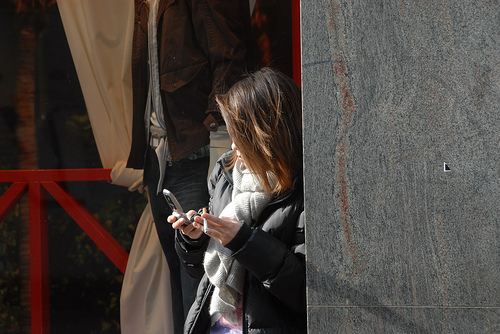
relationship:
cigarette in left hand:
[202, 206, 209, 234] [193, 214, 242, 246]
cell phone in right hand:
[163, 188, 193, 224] [166, 210, 203, 239]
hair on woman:
[214, 67, 301, 198] [168, 66, 307, 333]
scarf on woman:
[203, 158, 279, 316] [168, 66, 307, 333]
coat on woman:
[175, 151, 307, 333] [168, 66, 307, 333]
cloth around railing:
[56, 0, 175, 333] [0, 167, 131, 332]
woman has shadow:
[168, 66, 307, 333] [308, 261, 430, 333]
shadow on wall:
[308, 261, 430, 333] [301, 0, 500, 333]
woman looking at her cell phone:
[168, 66, 307, 333] [163, 188, 193, 224]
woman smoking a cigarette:
[168, 66, 307, 333] [202, 206, 209, 234]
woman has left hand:
[168, 66, 307, 333] [193, 214, 242, 246]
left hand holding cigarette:
[193, 214, 242, 246] [202, 206, 209, 234]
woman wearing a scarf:
[168, 66, 307, 333] [203, 158, 279, 316]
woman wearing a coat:
[168, 66, 307, 333] [175, 151, 307, 333]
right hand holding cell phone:
[166, 210, 203, 239] [163, 188, 193, 224]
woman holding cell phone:
[168, 66, 307, 333] [163, 188, 193, 224]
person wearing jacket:
[128, 1, 249, 333] [124, 2, 247, 171]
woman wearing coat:
[168, 66, 307, 333] [175, 151, 307, 333]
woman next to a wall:
[168, 66, 307, 333] [301, 0, 500, 333]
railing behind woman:
[0, 167, 131, 332] [168, 66, 307, 333]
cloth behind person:
[56, 0, 175, 333] [128, 1, 249, 333]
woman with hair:
[168, 66, 307, 333] [214, 67, 301, 198]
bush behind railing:
[57, 192, 151, 332] [0, 167, 131, 332]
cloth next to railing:
[56, 0, 175, 333] [0, 167, 131, 332]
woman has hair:
[168, 66, 307, 333] [214, 67, 301, 198]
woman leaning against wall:
[168, 66, 307, 333] [301, 0, 500, 333]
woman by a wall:
[168, 66, 307, 333] [301, 0, 500, 333]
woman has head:
[168, 66, 307, 333] [223, 73, 303, 172]